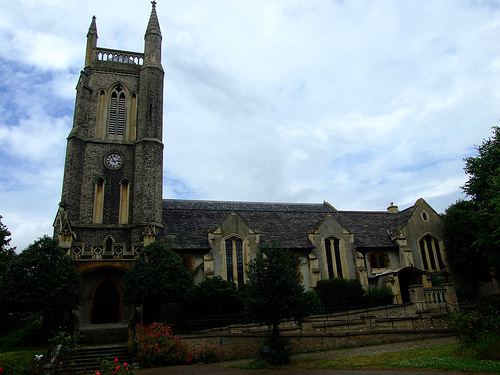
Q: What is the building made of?
A: Stone.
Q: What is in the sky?
A: Clouds.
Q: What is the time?
A: 2:55.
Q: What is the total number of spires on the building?
A: 2.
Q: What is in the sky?
A: Clouds.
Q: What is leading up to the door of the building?
A: Steps.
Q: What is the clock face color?
A: White.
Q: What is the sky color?
A: Blue.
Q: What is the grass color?
A: Green.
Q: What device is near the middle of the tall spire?
A: A clock.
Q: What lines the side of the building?
A: Trees.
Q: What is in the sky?
A: Clouds.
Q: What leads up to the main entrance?
A: Stairs.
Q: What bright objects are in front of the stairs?
A: Flowers.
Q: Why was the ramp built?
A: For wheelchair accessibility.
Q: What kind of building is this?
A: An old church.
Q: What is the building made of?
A: Grey stone.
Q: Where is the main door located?
A: Beneath a stone arch.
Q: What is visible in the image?
A: Building.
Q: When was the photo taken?
A: Daytime.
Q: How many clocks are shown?
A: One.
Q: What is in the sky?
A: Clouds.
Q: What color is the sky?
A: Blue.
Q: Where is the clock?
A: On the building.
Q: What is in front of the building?
A: Trees.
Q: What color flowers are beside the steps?
A: Pink.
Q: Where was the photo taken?
A: In front of a church.